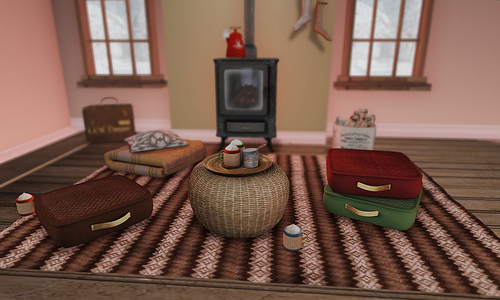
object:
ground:
[364, 147, 394, 192]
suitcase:
[30, 175, 155, 249]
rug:
[1, 135, 498, 297]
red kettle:
[222, 25, 247, 59]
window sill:
[76, 71, 175, 92]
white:
[333, 118, 377, 150]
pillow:
[326, 143, 425, 198]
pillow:
[321, 176, 425, 231]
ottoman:
[185, 150, 291, 238]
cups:
[217, 137, 259, 169]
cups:
[282, 223, 309, 251]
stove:
[212, 0, 280, 152]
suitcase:
[327, 142, 423, 198]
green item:
[328, 197, 413, 231]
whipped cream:
[226, 138, 243, 151]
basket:
[187, 138, 290, 239]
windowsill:
[335, 70, 432, 85]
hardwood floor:
[3, 138, 498, 239]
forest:
[355, 2, 419, 75]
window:
[87, 2, 150, 79]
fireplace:
[213, 57, 279, 137]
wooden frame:
[331, 0, 439, 91]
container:
[322, 184, 423, 230]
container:
[326, 148, 422, 198]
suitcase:
[320, 181, 427, 231]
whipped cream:
[283, 223, 302, 235]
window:
[348, 0, 424, 80]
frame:
[72, 2, 169, 89]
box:
[333, 120, 378, 150]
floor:
[2, 134, 493, 296]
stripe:
[0, 157, 500, 296]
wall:
[62, 7, 494, 127]